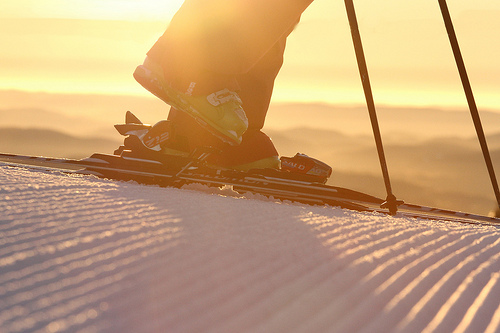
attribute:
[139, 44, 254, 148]
ski boot — green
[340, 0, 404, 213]
pole — black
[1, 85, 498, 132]
hill — hazy, distant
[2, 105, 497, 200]
hill — hazy, distant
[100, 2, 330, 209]
skier — downhill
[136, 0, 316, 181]
skier — waiting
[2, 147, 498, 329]
snow — raked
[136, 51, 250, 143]
boot — green, unmounted